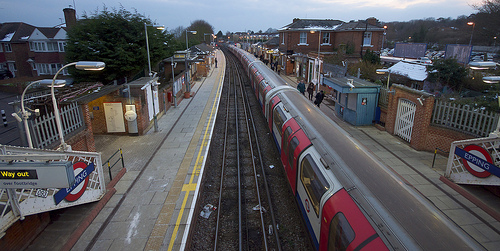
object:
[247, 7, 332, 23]
clouds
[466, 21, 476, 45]
lights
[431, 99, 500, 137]
fence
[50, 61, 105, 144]
lights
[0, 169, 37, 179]
signboard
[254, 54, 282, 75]
people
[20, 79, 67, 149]
lampposts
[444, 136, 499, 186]
sign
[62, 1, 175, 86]
tree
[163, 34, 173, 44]
green leaf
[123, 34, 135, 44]
green leaf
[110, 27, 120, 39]
green leaf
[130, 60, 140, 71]
green leaf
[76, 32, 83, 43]
green leaf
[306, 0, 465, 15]
clouds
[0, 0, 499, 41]
sky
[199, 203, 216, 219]
garbage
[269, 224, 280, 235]
garbage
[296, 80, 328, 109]
people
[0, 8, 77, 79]
brick building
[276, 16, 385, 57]
brick building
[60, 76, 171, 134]
brick building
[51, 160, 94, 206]
symbol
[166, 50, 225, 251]
line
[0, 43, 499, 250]
pavement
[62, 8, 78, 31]
chimney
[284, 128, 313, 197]
red door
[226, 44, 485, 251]
train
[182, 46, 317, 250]
track